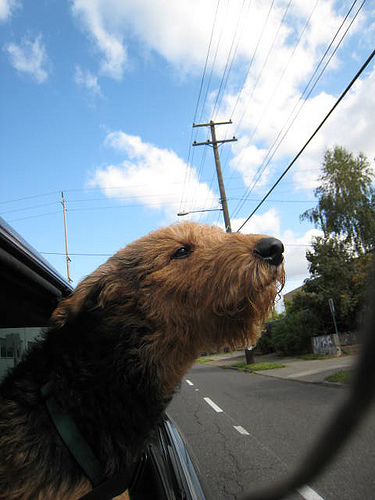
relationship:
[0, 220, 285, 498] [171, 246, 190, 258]
dog has eye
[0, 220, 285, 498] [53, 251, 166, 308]
dog has ear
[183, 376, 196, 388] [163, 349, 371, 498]
line on concrete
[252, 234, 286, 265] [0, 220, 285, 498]
nose of dog